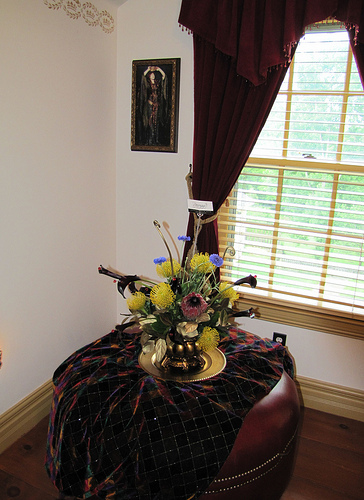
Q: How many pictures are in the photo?
A: One.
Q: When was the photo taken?
A: In the daytime.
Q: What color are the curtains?
A: Red.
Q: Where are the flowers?
A: On a tablecloth.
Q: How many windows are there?
A: One.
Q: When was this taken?
A: During the day.